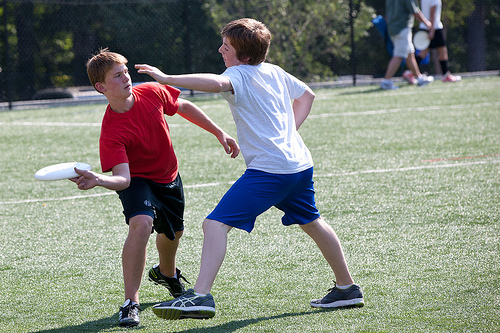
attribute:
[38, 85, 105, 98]
car — white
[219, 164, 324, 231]
shorts — blue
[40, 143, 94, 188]
plate — white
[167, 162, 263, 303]
leg — raised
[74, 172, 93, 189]
hand — bent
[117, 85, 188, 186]
shirt — red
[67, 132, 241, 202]
hands — apart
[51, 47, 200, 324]
boy — light-skinned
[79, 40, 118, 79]
hair — short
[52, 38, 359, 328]
kids — playing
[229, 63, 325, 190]
shirt — white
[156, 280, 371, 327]
shoes — grey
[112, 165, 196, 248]
shorts — black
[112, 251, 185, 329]
shoes — black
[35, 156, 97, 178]
disk — white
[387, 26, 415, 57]
shorts — white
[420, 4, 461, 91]
man — walking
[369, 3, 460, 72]
people — walking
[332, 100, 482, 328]
field — green